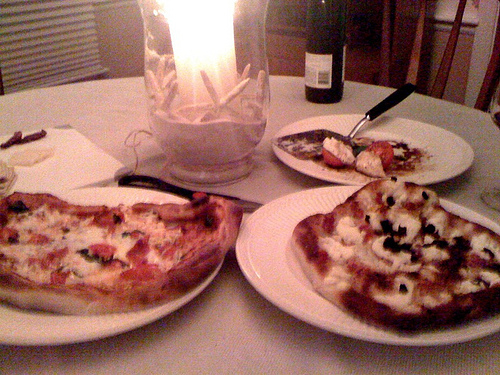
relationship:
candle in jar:
[165, 0, 236, 122] [136, 2, 268, 184]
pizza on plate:
[287, 177, 499, 337] [234, 185, 498, 347]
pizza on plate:
[2, 193, 244, 310] [2, 260, 224, 345]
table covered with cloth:
[4, 65, 497, 370] [1, 71, 499, 373]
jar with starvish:
[136, 2, 268, 184] [109, 11, 314, 167]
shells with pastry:
[321, 136, 387, 181] [324, 125, 398, 176]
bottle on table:
[295, 2, 359, 107] [4, 65, 497, 370]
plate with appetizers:
[7, 122, 148, 197] [1, 128, 57, 179]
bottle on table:
[302, 2, 346, 104] [4, 65, 497, 370]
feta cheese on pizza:
[395, 217, 422, 240] [287, 177, 499, 337]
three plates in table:
[5, 109, 498, 356] [4, 65, 497, 370]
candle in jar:
[172, 7, 235, 122] [136, 2, 268, 187]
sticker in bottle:
[300, 48, 337, 93] [298, 1, 348, 108]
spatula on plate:
[272, 76, 422, 159] [265, 111, 476, 189]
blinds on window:
[9, 8, 139, 106] [8, 5, 98, 85]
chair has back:
[371, 1, 499, 112] [342, 5, 496, 95]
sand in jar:
[149, 98, 269, 178] [136, 2, 268, 184]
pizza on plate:
[2, 193, 236, 310] [4, 171, 227, 351]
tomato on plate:
[330, 131, 390, 189] [422, 102, 489, 197]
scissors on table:
[112, 166, 258, 218] [4, 65, 497, 370]